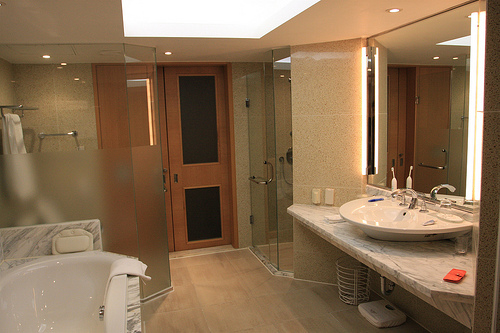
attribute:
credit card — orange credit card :
[432, 264, 469, 292]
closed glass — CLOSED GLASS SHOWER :
[57, 63, 147, 165]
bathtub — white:
[21, 260, 118, 316]